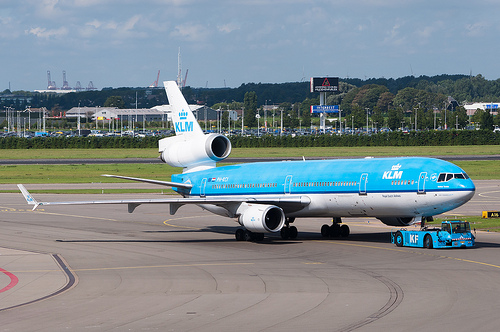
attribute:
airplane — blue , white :
[14, 77, 476, 242]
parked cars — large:
[259, 121, 449, 141]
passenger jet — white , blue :
[18, 80, 475, 231]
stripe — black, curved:
[3, 244, 84, 304]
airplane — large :
[130, 49, 490, 276]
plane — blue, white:
[151, 107, 477, 261]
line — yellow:
[446, 254, 496, 271]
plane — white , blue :
[123, 151, 498, 245]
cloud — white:
[26, 25, 66, 38]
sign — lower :
[314, 78, 339, 93]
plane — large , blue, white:
[17, 79, 474, 243]